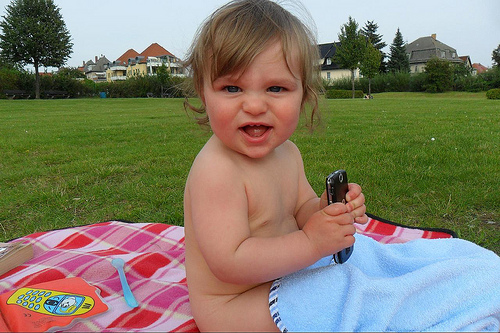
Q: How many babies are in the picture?
A: 1.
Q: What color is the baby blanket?
A: Blue.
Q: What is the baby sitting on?
A: A blanket.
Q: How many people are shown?
A: 1.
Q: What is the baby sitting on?
A: Blanket.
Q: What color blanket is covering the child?
A: Blue.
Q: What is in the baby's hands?
A: Cell Phone.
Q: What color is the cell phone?
A: Black and silver.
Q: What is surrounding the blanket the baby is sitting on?
A: Grass.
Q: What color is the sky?
A: Blue.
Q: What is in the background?
A: Houses.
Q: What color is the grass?
A: Green.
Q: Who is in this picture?
A: A baby.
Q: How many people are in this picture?
A: One.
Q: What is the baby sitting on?
A: A blanket.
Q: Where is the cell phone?
A: In the baby's hands.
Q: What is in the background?
A: Houses.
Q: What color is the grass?
A: Green.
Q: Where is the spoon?
A: Behind the baby.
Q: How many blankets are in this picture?
A: Two.